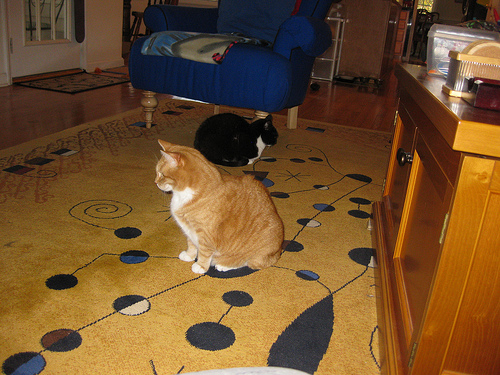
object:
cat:
[153, 138, 286, 277]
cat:
[191, 113, 280, 168]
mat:
[6, 65, 126, 96]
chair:
[125, 0, 333, 130]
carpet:
[0, 95, 392, 375]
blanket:
[139, 30, 274, 65]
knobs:
[394, 146, 411, 168]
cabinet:
[367, 59, 499, 375]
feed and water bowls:
[334, 73, 382, 95]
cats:
[153, 108, 284, 276]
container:
[426, 21, 499, 81]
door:
[5, 0, 84, 84]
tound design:
[181, 319, 239, 351]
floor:
[0, 68, 400, 156]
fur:
[170, 187, 200, 248]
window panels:
[23, 0, 73, 46]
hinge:
[7, 37, 14, 55]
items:
[426, 21, 499, 114]